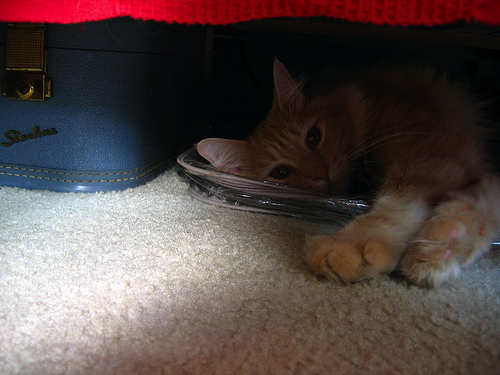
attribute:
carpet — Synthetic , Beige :
[3, 171, 498, 366]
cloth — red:
[1, 0, 484, 27]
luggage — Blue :
[2, 19, 210, 194]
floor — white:
[2, 165, 482, 371]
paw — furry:
[297, 209, 414, 285]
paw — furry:
[392, 229, 473, 292]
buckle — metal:
[10, 71, 42, 105]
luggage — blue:
[2, 24, 249, 198]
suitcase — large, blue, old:
[1, 22, 248, 196]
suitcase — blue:
[2, 25, 227, 197]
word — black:
[2, 120, 60, 154]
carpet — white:
[4, 213, 289, 371]